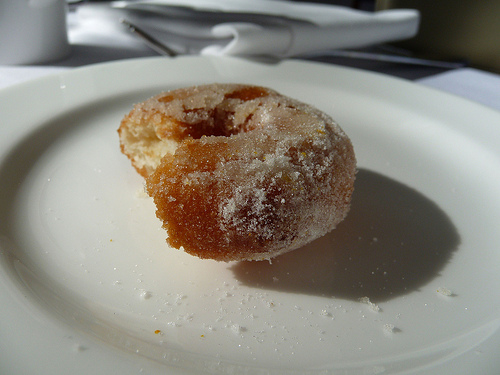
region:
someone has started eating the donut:
[115, 77, 356, 262]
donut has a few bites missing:
[111, 80, 354, 263]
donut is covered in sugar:
[110, 80, 352, 262]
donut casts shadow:
[117, 80, 355, 263]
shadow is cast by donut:
[226, 164, 460, 306]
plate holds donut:
[1, 56, 498, 373]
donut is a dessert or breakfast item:
[119, 81, 356, 264]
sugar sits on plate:
[75, 262, 460, 344]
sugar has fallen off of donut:
[81, 267, 458, 349]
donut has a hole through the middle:
[178, 99, 256, 146]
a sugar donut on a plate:
[112, 77, 374, 267]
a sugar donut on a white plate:
[116, 76, 367, 271]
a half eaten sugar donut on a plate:
[109, 72, 366, 264]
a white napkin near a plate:
[63, 0, 428, 62]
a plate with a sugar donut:
[2, 54, 499, 373]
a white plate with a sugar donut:
[2, 55, 497, 370]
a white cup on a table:
[0, 2, 74, 69]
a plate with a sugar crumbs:
[0, 52, 497, 373]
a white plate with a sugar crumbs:
[0, 52, 498, 372]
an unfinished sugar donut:
[116, 77, 361, 267]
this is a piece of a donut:
[115, 78, 362, 267]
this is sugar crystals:
[135, 277, 455, 345]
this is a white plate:
[5, 51, 497, 370]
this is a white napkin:
[76, 4, 423, 59]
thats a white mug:
[0, 1, 74, 67]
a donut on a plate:
[5, 50, 497, 372]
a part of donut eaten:
[113, 86, 184, 263]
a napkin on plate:
[74, 0, 421, 56]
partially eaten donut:
[108, 70, 350, 256]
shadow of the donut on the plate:
[237, 146, 457, 298]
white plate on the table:
[8, 58, 498, 374]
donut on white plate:
[3, 52, 494, 374]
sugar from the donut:
[58, 246, 468, 373]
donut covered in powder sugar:
[134, 96, 352, 262]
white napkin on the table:
[110, 7, 435, 57]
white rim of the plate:
[7, 61, 497, 368]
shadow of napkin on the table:
[333, 43, 459, 83]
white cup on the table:
[0, 0, 75, 67]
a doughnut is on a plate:
[105, 74, 372, 279]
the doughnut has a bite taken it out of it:
[115, 80, 207, 258]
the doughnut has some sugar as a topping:
[165, 80, 341, 259]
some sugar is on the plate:
[152, 274, 432, 354]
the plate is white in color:
[6, 62, 486, 372]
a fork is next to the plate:
[123, 13, 470, 79]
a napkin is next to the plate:
[79, 1, 399, 58]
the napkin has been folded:
[86, 15, 414, 57]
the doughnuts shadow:
[235, 155, 465, 323]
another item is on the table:
[3, 3, 82, 65]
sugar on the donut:
[240, 119, 344, 209]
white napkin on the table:
[86, 1, 434, 68]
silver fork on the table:
[117, 15, 469, 88]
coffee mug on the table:
[0, 0, 72, 51]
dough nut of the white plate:
[106, 76, 355, 266]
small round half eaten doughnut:
[117, 84, 357, 263]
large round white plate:
[0, 55, 498, 372]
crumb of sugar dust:
[138, 287, 153, 300]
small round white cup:
[2, 1, 72, 67]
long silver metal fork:
[121, 16, 473, 66]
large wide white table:
[0, 19, 497, 113]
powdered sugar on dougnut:
[215, 149, 330, 246]